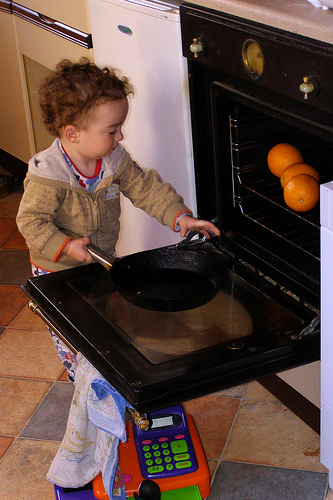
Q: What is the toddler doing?
A: Playing with the oven.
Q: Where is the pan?
A: On top of the oven door.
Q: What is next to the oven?
A: A refrigerator.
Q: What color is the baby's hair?
A: Brown.